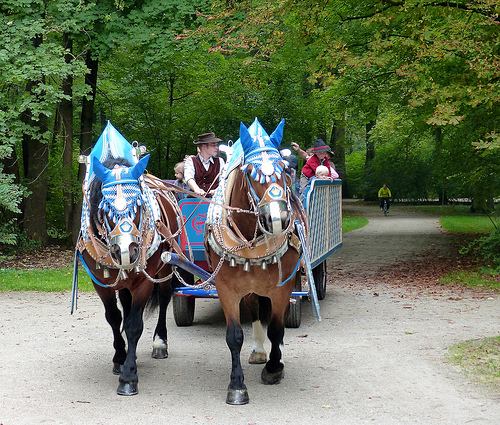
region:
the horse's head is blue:
[190, 122, 342, 223]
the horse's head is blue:
[213, 162, 297, 259]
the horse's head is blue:
[190, 87, 342, 298]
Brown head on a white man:
[191, 134, 220, 144]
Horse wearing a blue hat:
[229, 116, 304, 187]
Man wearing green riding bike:
[376, 183, 395, 210]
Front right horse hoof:
[223, 382, 250, 404]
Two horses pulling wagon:
[58, 122, 353, 408]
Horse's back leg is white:
[251, 320, 264, 365]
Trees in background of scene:
[2, 1, 497, 147]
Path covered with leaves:
[346, 200, 452, 325]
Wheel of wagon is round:
[170, 266, 200, 328]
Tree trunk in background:
[23, 120, 48, 251]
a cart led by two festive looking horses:
[65, 114, 348, 409]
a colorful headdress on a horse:
[231, 117, 291, 177]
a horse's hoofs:
[225, 345, 290, 407]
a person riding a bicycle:
[376, 181, 395, 216]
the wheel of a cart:
[172, 296, 196, 328]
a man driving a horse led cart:
[181, 132, 225, 203]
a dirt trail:
[361, 218, 429, 421]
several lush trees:
[3, 12, 233, 110]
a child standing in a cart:
[296, 140, 333, 164]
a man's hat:
[192, 134, 223, 144]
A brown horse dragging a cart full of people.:
[201, 112, 307, 404]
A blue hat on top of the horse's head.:
[237, 117, 287, 182]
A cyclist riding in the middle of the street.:
[375, 180, 393, 220]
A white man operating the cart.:
[182, 130, 225, 198]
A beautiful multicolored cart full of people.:
[170, 128, 340, 327]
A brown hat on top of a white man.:
[191, 131, 224, 145]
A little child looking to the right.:
[170, 161, 189, 200]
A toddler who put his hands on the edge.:
[313, 164, 334, 182]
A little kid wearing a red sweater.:
[300, 139, 331, 177]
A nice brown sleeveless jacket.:
[187, 153, 220, 197]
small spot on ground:
[64, 393, 115, 402]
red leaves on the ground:
[352, 241, 492, 301]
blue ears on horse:
[228, 113, 309, 145]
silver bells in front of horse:
[215, 247, 316, 275]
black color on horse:
[191, 313, 266, 344]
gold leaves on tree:
[188, 3, 285, 66]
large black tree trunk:
[16, 122, 71, 249]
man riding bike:
[368, 173, 416, 218]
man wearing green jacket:
[371, 178, 397, 200]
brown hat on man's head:
[160, 106, 224, 152]